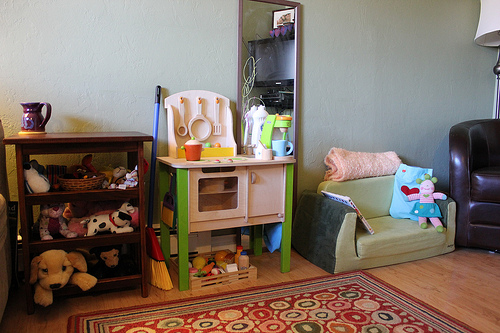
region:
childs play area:
[6, 16, 461, 306]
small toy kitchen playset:
[157, 83, 302, 300]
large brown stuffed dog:
[25, 247, 97, 312]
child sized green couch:
[305, 152, 464, 267]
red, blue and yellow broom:
[142, 81, 179, 295]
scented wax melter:
[17, 95, 52, 139]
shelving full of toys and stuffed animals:
[23, 147, 138, 298]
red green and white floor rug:
[256, 273, 439, 331]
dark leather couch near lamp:
[449, 0, 499, 238]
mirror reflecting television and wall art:
[235, 0, 302, 111]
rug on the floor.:
[301, 291, 343, 313]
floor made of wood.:
[450, 272, 479, 291]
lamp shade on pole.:
[475, 7, 497, 31]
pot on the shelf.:
[21, 94, 51, 120]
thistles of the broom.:
[150, 248, 159, 278]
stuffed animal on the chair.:
[414, 184, 438, 232]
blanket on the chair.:
[335, 148, 393, 173]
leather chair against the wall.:
[467, 136, 493, 225]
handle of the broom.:
[152, 89, 161, 128]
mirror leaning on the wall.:
[255, 15, 288, 45]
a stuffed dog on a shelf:
[27, 248, 102, 313]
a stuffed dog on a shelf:
[86, 199, 146, 240]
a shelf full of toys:
[2, 133, 152, 301]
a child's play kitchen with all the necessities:
[147, 83, 301, 293]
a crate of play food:
[187, 243, 262, 296]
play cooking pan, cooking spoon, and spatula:
[177, 95, 224, 142]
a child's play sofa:
[318, 162, 458, 278]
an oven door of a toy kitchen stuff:
[188, 168, 249, 234]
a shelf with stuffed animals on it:
[28, 188, 148, 235]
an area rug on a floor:
[316, 272, 440, 332]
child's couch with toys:
[301, 164, 471, 274]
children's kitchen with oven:
[158, 75, 302, 293]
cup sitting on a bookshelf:
[12, 90, 66, 141]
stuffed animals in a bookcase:
[2, 137, 144, 302]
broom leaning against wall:
[135, 72, 180, 299]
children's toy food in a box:
[181, 237, 269, 316]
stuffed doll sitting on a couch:
[335, 162, 457, 257]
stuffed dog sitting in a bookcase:
[22, 243, 100, 307]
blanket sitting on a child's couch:
[311, 137, 458, 193]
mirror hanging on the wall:
[227, 2, 322, 104]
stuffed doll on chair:
[410, 175, 445, 225]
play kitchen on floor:
[167, 90, 294, 286]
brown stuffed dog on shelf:
[29, 249, 96, 306]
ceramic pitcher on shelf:
[21, 102, 51, 134]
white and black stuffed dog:
[81, 208, 132, 236]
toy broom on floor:
[151, 83, 173, 292]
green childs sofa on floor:
[296, 173, 456, 275]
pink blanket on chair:
[323, 145, 399, 178]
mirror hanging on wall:
[236, 3, 298, 161]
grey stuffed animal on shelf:
[39, 201, 73, 239]